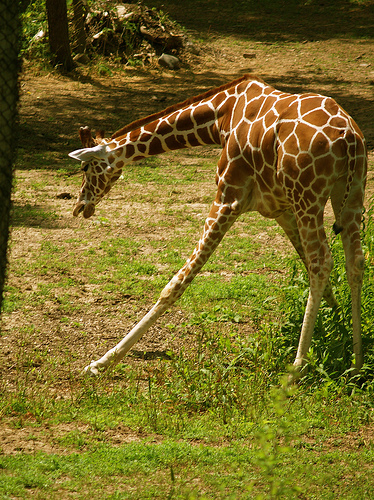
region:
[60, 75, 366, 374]
bi8g giraffe on a field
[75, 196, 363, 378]
four legs of big giraffe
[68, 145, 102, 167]
big left ear of big giraffe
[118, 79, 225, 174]
large neck of giraffe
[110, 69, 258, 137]
short brown hair in the loin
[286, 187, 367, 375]
two thin back legsof giraffe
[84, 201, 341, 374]
two front open legs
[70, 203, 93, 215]
small brown mouth open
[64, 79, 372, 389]
giraffe have brown dots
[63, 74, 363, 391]
big giraffe standing on green grass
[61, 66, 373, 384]
giraffe bending down to reach the ground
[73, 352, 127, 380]
giraffe's hooves are cloven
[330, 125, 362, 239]
giraffe has a long thin tail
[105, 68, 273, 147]
giraffe has a short brown mane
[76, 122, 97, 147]
giraffe has short tufted horns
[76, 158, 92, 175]
giraffe has dark gentle eyes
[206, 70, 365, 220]
giraffe's spots fit together like an interlocking mosaic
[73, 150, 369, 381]
giraffe's front legs are longer than its back legs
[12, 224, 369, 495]
giraffe is standing on a sparse grassy patch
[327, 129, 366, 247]
tuft of fur at the end of the giraffe's tail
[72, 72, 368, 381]
The mature adult giraffe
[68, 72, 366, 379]
The curious looking giraffe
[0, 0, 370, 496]
A giraffe in a park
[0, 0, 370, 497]
The limited grass growing park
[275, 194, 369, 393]
The thick vegetation on the right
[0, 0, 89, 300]
The tree trunks on the left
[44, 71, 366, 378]
The tall legged giraffe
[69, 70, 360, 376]
The brown spotted tall giraffe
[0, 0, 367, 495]
A bright day in a park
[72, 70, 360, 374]
A long necked giraffe grazing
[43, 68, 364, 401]
A giraffe is standing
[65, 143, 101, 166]
Ear of a giraffe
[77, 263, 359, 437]
Tall grass near a giraffe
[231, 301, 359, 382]
Group of tall grass near a giraffe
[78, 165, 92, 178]
Eye of a giraffe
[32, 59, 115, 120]
Shadows from trees in the background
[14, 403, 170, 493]
Patches of green and brown grass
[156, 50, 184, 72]
A rock in the background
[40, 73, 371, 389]
giraffe is white with orange spots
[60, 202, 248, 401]
the giraffe is sticking its leg out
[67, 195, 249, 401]
the giraffe's leg is long and skinny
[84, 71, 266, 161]
giraffe has short orange hair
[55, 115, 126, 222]
giraffe has horns on its head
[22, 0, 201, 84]
trees are present in the background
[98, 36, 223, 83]
rocks on the ground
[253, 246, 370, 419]
giraffe standing in tall grass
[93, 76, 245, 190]
the giraffe has a very long neck